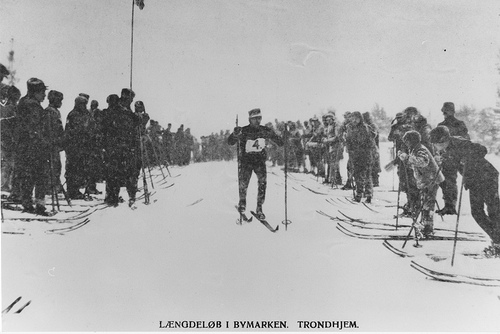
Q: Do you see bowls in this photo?
A: No, there are no bowls.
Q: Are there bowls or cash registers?
A: No, there are no bowls or cash registers.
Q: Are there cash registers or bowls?
A: No, there are no bowls or cash registers.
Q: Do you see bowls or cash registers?
A: No, there are no bowls or cash registers.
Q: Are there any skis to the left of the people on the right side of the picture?
A: Yes, there is a ski to the left of the people.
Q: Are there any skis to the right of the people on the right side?
A: No, the ski is to the left of the people.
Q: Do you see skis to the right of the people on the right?
A: No, the ski is to the left of the people.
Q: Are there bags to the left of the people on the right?
A: No, there is a ski to the left of the people.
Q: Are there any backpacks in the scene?
A: No, there are no backpacks.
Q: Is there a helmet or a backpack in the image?
A: No, there are no backpacks or helmets.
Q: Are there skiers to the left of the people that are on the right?
A: Yes, there is a skier to the left of the people.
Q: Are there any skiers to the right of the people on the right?
A: No, the skier is to the left of the people.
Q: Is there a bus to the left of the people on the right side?
A: No, there is a skier to the left of the people.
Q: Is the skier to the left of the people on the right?
A: Yes, the skier is to the left of the people.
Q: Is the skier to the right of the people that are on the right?
A: No, the skier is to the left of the people.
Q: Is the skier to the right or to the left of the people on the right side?
A: The skier is to the left of the people.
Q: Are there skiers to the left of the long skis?
A: Yes, there is a skier to the left of the skis.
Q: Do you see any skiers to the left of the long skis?
A: Yes, there is a skier to the left of the skis.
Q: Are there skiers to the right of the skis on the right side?
A: No, the skier is to the left of the skis.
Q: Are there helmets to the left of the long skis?
A: No, there is a skier to the left of the skis.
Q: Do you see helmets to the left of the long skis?
A: No, there is a skier to the left of the skis.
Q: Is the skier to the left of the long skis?
A: Yes, the skier is to the left of the skis.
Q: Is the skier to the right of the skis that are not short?
A: No, the skier is to the left of the skis.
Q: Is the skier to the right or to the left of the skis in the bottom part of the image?
A: The skier is to the left of the skis.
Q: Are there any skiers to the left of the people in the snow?
A: Yes, there is a skier to the left of the people.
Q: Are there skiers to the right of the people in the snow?
A: No, the skier is to the left of the people.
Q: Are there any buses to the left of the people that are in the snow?
A: No, there is a skier to the left of the people.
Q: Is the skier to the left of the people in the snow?
A: Yes, the skier is to the left of the people.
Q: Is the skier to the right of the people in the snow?
A: No, the skier is to the left of the people.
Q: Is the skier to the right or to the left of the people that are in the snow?
A: The skier is to the left of the people.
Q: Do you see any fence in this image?
A: No, there are no fences.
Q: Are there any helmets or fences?
A: No, there are no fences or helmets.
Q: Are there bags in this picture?
A: No, there are no bags.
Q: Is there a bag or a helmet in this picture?
A: No, there are no bags or helmets.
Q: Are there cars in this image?
A: No, there are no cars.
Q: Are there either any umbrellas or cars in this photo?
A: No, there are no cars or umbrellas.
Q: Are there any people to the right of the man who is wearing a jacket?
A: Yes, there are people to the right of the man.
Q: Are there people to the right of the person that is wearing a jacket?
A: Yes, there are people to the right of the man.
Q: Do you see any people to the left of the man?
A: No, the people are to the right of the man.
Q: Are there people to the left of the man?
A: No, the people are to the right of the man.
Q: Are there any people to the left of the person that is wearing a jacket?
A: No, the people are to the right of the man.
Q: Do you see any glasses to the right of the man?
A: No, there are people to the right of the man.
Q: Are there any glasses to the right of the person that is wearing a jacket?
A: No, there are people to the right of the man.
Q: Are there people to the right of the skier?
A: Yes, there are people to the right of the skier.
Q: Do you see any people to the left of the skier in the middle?
A: No, the people are to the right of the skier.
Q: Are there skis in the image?
A: Yes, there are skis.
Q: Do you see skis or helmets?
A: Yes, there are skis.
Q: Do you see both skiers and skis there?
A: Yes, there are both skis and a skier.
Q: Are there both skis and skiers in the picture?
A: Yes, there are both skis and a skier.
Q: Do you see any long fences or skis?
A: Yes, there are long skis.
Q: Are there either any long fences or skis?
A: Yes, there are long skis.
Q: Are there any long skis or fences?
A: Yes, there are long skis.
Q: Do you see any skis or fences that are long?
A: Yes, the skis are long.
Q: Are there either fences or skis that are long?
A: Yes, the skis are long.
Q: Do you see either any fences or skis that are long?
A: Yes, the skis are long.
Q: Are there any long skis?
A: Yes, there are long skis.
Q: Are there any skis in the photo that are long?
A: Yes, there are skis that are long.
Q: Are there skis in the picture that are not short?
A: Yes, there are long skis.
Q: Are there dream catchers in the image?
A: No, there are no dream catchers.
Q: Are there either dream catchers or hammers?
A: No, there are no dream catchers or hammers.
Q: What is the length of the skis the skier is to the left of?
A: The skis are long.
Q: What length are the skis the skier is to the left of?
A: The skis are long.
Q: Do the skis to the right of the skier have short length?
A: No, the skis are long.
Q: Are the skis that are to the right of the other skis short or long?
A: The skis are long.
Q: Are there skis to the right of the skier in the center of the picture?
A: Yes, there are skis to the right of the skier.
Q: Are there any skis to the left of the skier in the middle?
A: No, the skis are to the right of the skier.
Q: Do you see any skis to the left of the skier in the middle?
A: No, the skis are to the right of the skier.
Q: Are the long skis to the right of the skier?
A: Yes, the skis are to the right of the skier.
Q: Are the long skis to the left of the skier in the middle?
A: No, the skis are to the right of the skier.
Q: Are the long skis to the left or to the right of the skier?
A: The skis are to the right of the skier.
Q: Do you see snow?
A: Yes, there is snow.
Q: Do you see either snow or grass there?
A: Yes, there is snow.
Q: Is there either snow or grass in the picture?
A: Yes, there is snow.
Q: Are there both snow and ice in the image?
A: No, there is snow but no ice.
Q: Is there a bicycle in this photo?
A: No, there are no bicycles.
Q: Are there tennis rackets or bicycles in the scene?
A: No, there are no bicycles or tennis rackets.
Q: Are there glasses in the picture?
A: No, there are no glasses.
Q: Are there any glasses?
A: No, there are no glasses.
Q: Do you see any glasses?
A: No, there are no glasses.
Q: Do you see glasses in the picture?
A: No, there are no glasses.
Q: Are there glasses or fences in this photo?
A: No, there are no glasses or fences.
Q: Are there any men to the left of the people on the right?
A: Yes, there is a man to the left of the people.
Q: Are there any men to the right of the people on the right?
A: No, the man is to the left of the people.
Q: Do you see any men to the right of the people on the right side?
A: No, the man is to the left of the people.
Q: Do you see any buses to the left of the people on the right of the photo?
A: No, there is a man to the left of the people.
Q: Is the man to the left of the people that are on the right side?
A: Yes, the man is to the left of the people.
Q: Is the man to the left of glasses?
A: No, the man is to the left of the people.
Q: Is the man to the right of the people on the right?
A: No, the man is to the left of the people.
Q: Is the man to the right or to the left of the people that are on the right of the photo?
A: The man is to the left of the people.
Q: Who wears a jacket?
A: The man wears a jacket.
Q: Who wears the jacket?
A: The man wears a jacket.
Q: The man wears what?
A: The man wears a jacket.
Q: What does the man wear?
A: The man wears a jacket.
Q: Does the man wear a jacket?
A: Yes, the man wears a jacket.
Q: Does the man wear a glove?
A: No, the man wears a jacket.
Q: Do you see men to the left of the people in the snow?
A: Yes, there is a man to the left of the people.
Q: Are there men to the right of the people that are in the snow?
A: No, the man is to the left of the people.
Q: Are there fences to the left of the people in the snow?
A: No, there is a man to the left of the people.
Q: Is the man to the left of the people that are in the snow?
A: Yes, the man is to the left of the people.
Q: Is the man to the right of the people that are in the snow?
A: No, the man is to the left of the people.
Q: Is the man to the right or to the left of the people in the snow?
A: The man is to the left of the people.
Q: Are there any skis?
A: Yes, there are skis.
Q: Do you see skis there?
A: Yes, there are skis.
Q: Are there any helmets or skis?
A: Yes, there are skis.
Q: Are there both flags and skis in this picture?
A: Yes, there are both skis and a flag.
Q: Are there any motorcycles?
A: No, there are no motorcycles.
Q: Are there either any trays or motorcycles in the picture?
A: No, there are no motorcycles or trays.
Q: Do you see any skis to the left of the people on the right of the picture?
A: Yes, there are skis to the left of the people.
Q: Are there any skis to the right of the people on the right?
A: No, the skis are to the left of the people.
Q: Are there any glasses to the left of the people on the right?
A: No, there are skis to the left of the people.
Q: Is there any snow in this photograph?
A: Yes, there is snow.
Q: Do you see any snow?
A: Yes, there is snow.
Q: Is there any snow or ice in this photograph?
A: Yes, there is snow.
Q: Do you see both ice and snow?
A: No, there is snow but no ice.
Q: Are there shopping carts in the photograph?
A: No, there are no shopping carts.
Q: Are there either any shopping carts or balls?
A: No, there are no shopping carts or balls.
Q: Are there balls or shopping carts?
A: No, there are no shopping carts or balls.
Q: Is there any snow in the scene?
A: Yes, there is snow.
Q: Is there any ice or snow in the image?
A: Yes, there is snow.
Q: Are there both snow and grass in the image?
A: No, there is snow but no grass.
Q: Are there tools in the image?
A: No, there are no tools.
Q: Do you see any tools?
A: No, there are no tools.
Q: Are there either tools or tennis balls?
A: No, there are no tools or tennis balls.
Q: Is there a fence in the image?
A: No, there are no fences.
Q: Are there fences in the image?
A: No, there are no fences.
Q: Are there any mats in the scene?
A: No, there are no mats.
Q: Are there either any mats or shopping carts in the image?
A: No, there are no mats or shopping carts.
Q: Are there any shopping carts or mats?
A: No, there are no mats or shopping carts.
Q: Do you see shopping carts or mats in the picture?
A: No, there are no mats or shopping carts.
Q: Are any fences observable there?
A: No, there are no fences.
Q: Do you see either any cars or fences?
A: No, there are no fences or cars.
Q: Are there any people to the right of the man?
A: Yes, there are people to the right of the man.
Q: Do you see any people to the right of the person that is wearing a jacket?
A: Yes, there are people to the right of the man.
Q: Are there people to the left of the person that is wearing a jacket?
A: No, the people are to the right of the man.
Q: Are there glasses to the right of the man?
A: No, there are people to the right of the man.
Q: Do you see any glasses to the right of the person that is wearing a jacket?
A: No, there are people to the right of the man.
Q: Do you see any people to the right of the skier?
A: Yes, there are people to the right of the skier.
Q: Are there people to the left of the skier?
A: No, the people are to the right of the skier.